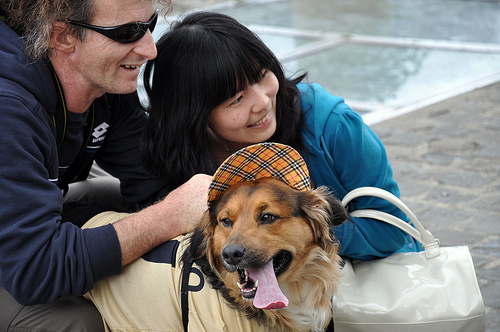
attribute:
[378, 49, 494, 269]
path — brown, cobblestone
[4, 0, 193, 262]
man — wearing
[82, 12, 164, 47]
sunglasses — black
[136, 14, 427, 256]
woman — Asian, smiling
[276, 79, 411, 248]
sweater — light blue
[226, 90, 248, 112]
eye — person's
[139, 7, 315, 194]
hair — black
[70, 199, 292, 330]
clothes — beige-colored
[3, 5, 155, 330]
man — wearing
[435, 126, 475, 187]
flooring — concrete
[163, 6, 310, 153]
woman — holding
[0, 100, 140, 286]
sweater. — dark blue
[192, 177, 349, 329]
dog — brown, black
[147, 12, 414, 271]
woman — holding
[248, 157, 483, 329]
purse — white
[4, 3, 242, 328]
man — wearing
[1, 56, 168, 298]
jacket — blue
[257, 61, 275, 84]
eye — person's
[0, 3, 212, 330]
man — pictured, older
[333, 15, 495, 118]
surface — glass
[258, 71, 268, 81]
eye — person's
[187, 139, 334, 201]
hat — plaid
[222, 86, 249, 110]
eye — person's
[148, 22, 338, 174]
woman — holding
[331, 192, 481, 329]
purse — white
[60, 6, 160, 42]
sun glasses — black